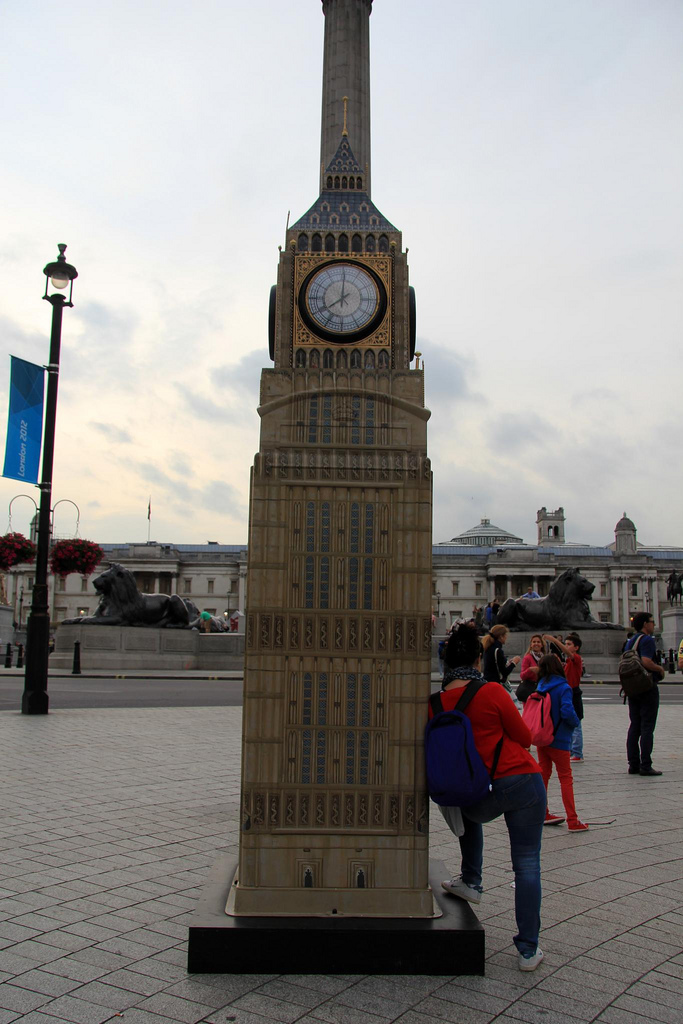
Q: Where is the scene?
A: A city corner.